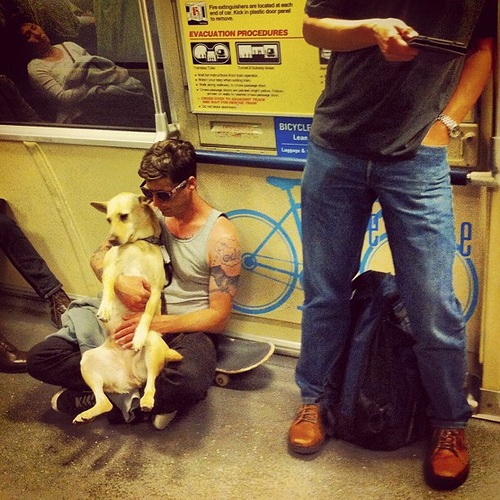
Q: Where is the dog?
A: In the man's lap.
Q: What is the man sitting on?
A: Skateboard.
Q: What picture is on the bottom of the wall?
A: Bicycle.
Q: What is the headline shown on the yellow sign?
A: EVACUATION PROCEDURES.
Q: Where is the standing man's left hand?
A: In his pocket.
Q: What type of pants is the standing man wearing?
A: Jeans.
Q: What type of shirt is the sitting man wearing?
A: Tank top.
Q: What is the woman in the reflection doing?
A: Sleeping.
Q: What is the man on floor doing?
A: Holding a dog.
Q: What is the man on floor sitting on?
A: Skateboard.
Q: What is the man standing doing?
A: Holding something.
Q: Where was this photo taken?
A: A subway train.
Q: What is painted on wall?
A: A bicycle.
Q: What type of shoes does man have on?
A: Brown laced shoes.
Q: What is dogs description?
A: A white dog.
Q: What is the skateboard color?
A: Black.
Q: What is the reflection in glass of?
A: A woman sleeping.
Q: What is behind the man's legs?
A: A blue backpack.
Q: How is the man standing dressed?
A: In t-shirt and jeans.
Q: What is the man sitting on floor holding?
A: A dog.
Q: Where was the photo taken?
A: Station.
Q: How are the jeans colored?
A: Blue.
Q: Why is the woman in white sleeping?
A: Resting.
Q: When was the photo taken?
A: Night.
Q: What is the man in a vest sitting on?
A: Skateboard.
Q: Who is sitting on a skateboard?
A: Young man.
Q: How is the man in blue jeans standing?
A: Leaning on one side.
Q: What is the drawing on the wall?
A: A bicycle.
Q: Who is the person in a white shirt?
A: A woman.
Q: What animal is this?
A: Dog.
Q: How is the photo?
A: Clear.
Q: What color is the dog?
A: White.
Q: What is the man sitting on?
A: Skateboard.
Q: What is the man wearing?
A: Glasses.